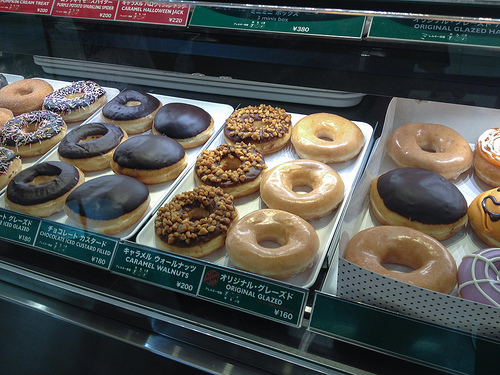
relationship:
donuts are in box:
[346, 115, 499, 305] [336, 83, 499, 346]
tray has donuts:
[140, 99, 375, 293] [159, 99, 369, 283]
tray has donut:
[6, 84, 238, 256] [0, 77, 53, 116]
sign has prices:
[7, 219, 312, 333] [7, 227, 301, 329]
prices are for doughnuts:
[7, 227, 301, 329] [0, 63, 498, 312]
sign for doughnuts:
[7, 219, 312, 333] [0, 63, 498, 312]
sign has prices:
[3, 3, 498, 60] [8, 4, 498, 46]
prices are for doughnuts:
[8, 4, 498, 46] [0, 63, 498, 312]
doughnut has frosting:
[466, 181, 499, 251] [471, 188, 499, 241]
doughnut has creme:
[59, 173, 159, 243] [69, 215, 150, 229]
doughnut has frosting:
[59, 173, 159, 243] [64, 173, 149, 221]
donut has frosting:
[110, 134, 189, 185] [112, 133, 186, 168]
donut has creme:
[110, 134, 189, 185] [123, 158, 196, 180]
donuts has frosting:
[151, 102, 215, 149] [156, 102, 209, 138]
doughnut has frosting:
[4, 159, 85, 221] [9, 161, 81, 199]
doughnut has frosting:
[55, 120, 135, 176] [58, 121, 123, 158]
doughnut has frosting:
[42, 80, 108, 122] [46, 81, 104, 112]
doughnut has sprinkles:
[42, 80, 108, 122] [42, 81, 107, 115]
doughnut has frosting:
[2, 107, 70, 159] [3, 112, 69, 146]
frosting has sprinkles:
[3, 112, 69, 146] [6, 115, 60, 141]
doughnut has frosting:
[155, 188, 236, 254] [154, 188, 237, 245]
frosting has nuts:
[154, 188, 237, 245] [160, 189, 232, 246]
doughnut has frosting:
[189, 140, 275, 206] [195, 143, 266, 187]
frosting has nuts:
[195, 143, 266, 187] [196, 142, 266, 184]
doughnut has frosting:
[221, 102, 297, 159] [228, 107, 292, 141]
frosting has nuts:
[228, 107, 292, 141] [229, 107, 291, 139]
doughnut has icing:
[59, 173, 159, 243] [64, 173, 149, 221]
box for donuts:
[336, 83, 499, 346] [346, 115, 499, 305]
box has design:
[336, 83, 499, 346] [336, 266, 498, 340]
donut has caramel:
[469, 119, 500, 191] [483, 131, 499, 160]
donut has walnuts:
[469, 119, 500, 191] [479, 126, 499, 162]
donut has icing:
[110, 131, 188, 188] [114, 134, 183, 165]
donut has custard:
[110, 131, 188, 188] [123, 158, 196, 180]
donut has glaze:
[99, 87, 165, 138] [102, 89, 158, 117]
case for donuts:
[2, 4, 498, 372] [0, 63, 498, 312]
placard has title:
[187, 3, 370, 45] [239, 7, 310, 32]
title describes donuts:
[239, 7, 310, 32] [159, 99, 369, 283]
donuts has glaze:
[385, 118, 473, 180] [388, 121, 475, 169]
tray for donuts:
[27, 38, 380, 117] [0, 63, 498, 312]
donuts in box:
[385, 118, 473, 180] [336, 83, 499, 346]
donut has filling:
[110, 131, 188, 188] [123, 158, 196, 180]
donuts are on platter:
[159, 99, 369, 283] [140, 99, 375, 293]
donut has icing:
[221, 102, 297, 159] [228, 107, 292, 141]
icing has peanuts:
[228, 107, 289, 139] [229, 107, 291, 139]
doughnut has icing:
[42, 80, 108, 122] [45, 81, 102, 109]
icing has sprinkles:
[45, 81, 102, 109] [42, 81, 107, 115]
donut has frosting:
[453, 243, 499, 312] [453, 244, 499, 319]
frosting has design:
[453, 244, 499, 319] [460, 245, 498, 305]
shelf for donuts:
[3, 5, 498, 49] [201, 0, 497, 18]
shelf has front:
[3, 5, 498, 49] [8, 10, 498, 46]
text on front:
[3, 3, 498, 60] [8, 10, 498, 46]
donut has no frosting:
[0, 77, 53, 118] [58, 121, 123, 158]